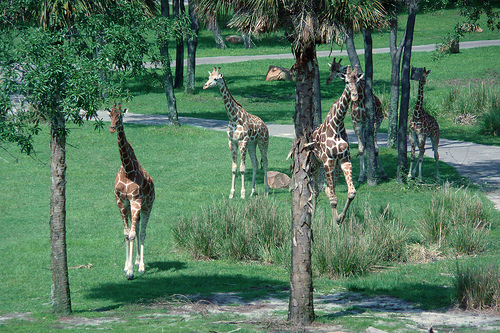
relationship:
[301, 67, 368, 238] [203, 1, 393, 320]
giraffe on tree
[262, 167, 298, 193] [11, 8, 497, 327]
rock on ground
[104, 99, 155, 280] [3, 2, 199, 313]
giraffe behind tree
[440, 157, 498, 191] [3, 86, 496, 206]
shadows on pavement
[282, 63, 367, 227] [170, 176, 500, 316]
giraffe running through bushes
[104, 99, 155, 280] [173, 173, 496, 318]
giraffe running through bushes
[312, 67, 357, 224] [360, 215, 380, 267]
giraffe running through bushes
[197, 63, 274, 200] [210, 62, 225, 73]
giraffe has horns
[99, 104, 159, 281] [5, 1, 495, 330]
giraffe in park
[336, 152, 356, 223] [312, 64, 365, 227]
leg of giraffe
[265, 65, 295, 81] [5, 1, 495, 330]
rock in park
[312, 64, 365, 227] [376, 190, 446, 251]
giraffe running through bushes